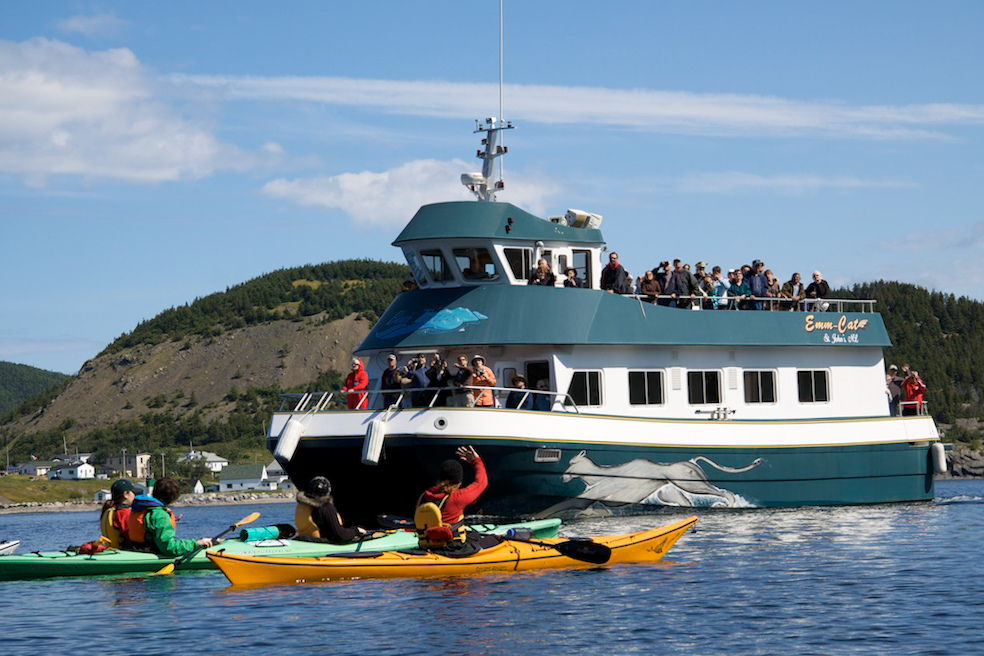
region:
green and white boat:
[273, 105, 960, 521]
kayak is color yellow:
[200, 515, 707, 597]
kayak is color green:
[10, 491, 556, 575]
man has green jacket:
[139, 467, 217, 561]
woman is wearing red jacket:
[409, 441, 498, 552]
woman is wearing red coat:
[329, 352, 375, 423]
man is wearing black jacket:
[377, 354, 402, 400]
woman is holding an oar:
[416, 424, 611, 571]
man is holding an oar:
[125, 474, 264, 582]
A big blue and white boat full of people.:
[258, 116, 945, 522]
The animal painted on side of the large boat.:
[527, 445, 758, 513]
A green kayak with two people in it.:
[0, 469, 254, 567]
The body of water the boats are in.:
[0, 472, 976, 643]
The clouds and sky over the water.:
[0, 0, 975, 368]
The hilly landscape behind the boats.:
[0, 254, 979, 501]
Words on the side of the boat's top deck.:
[801, 309, 865, 342]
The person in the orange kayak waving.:
[410, 441, 484, 546]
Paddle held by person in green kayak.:
[147, 508, 260, 572]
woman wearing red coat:
[340, 351, 372, 410]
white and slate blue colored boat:
[264, 110, 937, 507]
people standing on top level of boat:
[529, 249, 832, 312]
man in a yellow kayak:
[205, 440, 699, 587]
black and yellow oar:
[151, 505, 262, 580]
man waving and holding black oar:
[369, 440, 613, 567]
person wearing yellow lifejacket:
[288, 475, 368, 541]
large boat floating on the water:
[268, 114, 951, 513]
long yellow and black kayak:
[206, 513, 702, 586]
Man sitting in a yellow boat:
[205, 509, 699, 589]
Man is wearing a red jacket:
[418, 445, 484, 530]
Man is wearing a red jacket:
[341, 354, 369, 410]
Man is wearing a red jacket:
[899, 373, 927, 409]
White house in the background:
[217, 464, 266, 490]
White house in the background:
[47, 457, 94, 479]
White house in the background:
[105, 451, 154, 483]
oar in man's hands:
[485, 516, 619, 572]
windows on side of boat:
[565, 357, 855, 413]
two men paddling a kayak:
[86, 472, 199, 567]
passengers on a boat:
[332, 343, 532, 423]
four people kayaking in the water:
[4, 445, 700, 611]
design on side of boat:
[551, 444, 779, 514]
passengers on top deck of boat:
[589, 248, 888, 323]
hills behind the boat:
[122, 233, 375, 428]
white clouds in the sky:
[2, 106, 230, 193]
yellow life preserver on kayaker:
[413, 499, 446, 538]